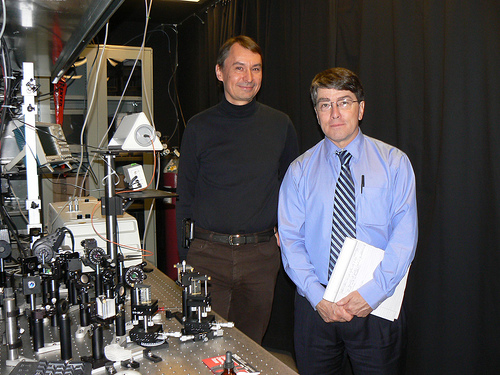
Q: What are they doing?
A: Standing.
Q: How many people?
A: 2.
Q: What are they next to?
A: Tools.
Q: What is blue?
A: Shirt.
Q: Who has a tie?
A: The man.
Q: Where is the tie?
A: Around neck.